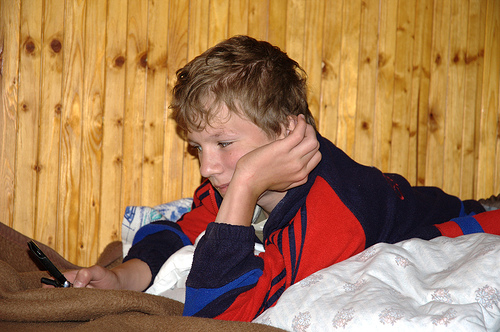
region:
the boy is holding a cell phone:
[22, 32, 498, 308]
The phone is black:
[22, 234, 77, 290]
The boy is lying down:
[36, 34, 497, 318]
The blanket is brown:
[3, 227, 273, 329]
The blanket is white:
[255, 232, 493, 329]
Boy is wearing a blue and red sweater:
[32, 28, 498, 315]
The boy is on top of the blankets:
[6, 29, 498, 326]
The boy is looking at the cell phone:
[21, 37, 498, 309]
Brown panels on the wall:
[4, 4, 494, 255]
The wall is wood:
[5, 3, 495, 263]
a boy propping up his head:
[116, 47, 323, 322]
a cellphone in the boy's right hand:
[31, 239, 125, 293]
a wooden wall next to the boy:
[1, 46, 497, 236]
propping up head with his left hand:
[173, 51, 322, 319]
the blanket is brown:
[0, 231, 262, 328]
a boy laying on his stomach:
[148, 49, 498, 244]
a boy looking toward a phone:
[26, 49, 319, 285]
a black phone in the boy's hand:
[28, 49, 447, 289]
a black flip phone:
[26, 230, 94, 292]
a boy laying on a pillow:
[166, 232, 498, 329]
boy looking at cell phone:
[37, 31, 494, 324]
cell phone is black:
[15, 231, 80, 291]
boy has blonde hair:
[165, 31, 316, 141]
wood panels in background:
[0, 3, 498, 265]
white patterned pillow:
[251, 232, 493, 330]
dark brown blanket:
[2, 220, 282, 330]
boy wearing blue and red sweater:
[122, 137, 494, 327]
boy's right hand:
[212, 105, 323, 226]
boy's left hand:
[48, 254, 158, 309]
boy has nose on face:
[188, 136, 228, 181]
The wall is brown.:
[5, 2, 499, 235]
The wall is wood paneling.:
[1, 2, 488, 223]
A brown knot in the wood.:
[47, 34, 68, 59]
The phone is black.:
[26, 248, 77, 295]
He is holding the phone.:
[18, 237, 118, 295]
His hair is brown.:
[158, 23, 325, 140]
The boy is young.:
[8, 63, 497, 315]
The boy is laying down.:
[11, 23, 495, 295]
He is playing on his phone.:
[3, 25, 478, 330]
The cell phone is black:
[29, 240, 69, 283]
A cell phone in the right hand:
[24, 238, 149, 291]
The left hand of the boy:
[236, 120, 316, 194]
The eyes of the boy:
[193, 137, 234, 152]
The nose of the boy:
[202, 146, 219, 175]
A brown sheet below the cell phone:
[3, 224, 284, 330]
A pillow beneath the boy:
[125, 195, 499, 330]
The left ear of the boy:
[279, 115, 296, 138]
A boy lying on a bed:
[63, 38, 495, 320]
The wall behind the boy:
[0, 2, 499, 264]